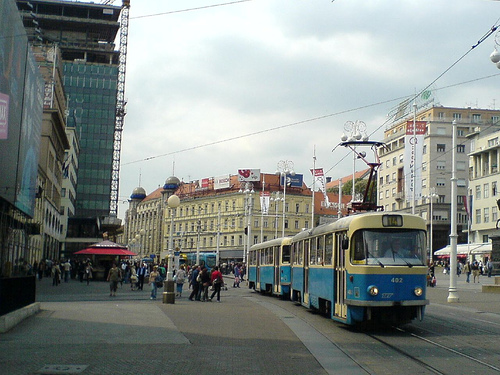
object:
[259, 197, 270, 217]
sign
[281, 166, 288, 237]
pole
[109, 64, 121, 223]
tower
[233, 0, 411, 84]
clouds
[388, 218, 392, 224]
number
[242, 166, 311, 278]
building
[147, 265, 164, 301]
woman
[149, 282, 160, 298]
blue jeans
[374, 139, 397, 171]
ground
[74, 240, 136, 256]
red canopy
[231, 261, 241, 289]
people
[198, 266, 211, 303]
people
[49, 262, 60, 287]
people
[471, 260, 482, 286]
people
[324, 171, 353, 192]
ground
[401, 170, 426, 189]
ground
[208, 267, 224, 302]
people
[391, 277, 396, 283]
white numbers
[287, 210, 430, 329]
front car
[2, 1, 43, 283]
building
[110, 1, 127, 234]
scaffolding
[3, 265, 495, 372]
street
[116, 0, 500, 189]
skies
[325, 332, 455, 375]
tracks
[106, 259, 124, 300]
person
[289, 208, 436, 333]
trolley car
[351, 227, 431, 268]
windshield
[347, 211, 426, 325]
front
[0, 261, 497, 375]
ground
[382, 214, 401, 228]
fourteen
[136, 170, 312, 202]
roof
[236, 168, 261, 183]
sign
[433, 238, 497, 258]
awning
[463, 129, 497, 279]
building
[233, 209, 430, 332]
bus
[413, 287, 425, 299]
headlight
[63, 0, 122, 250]
building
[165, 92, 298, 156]
clouds